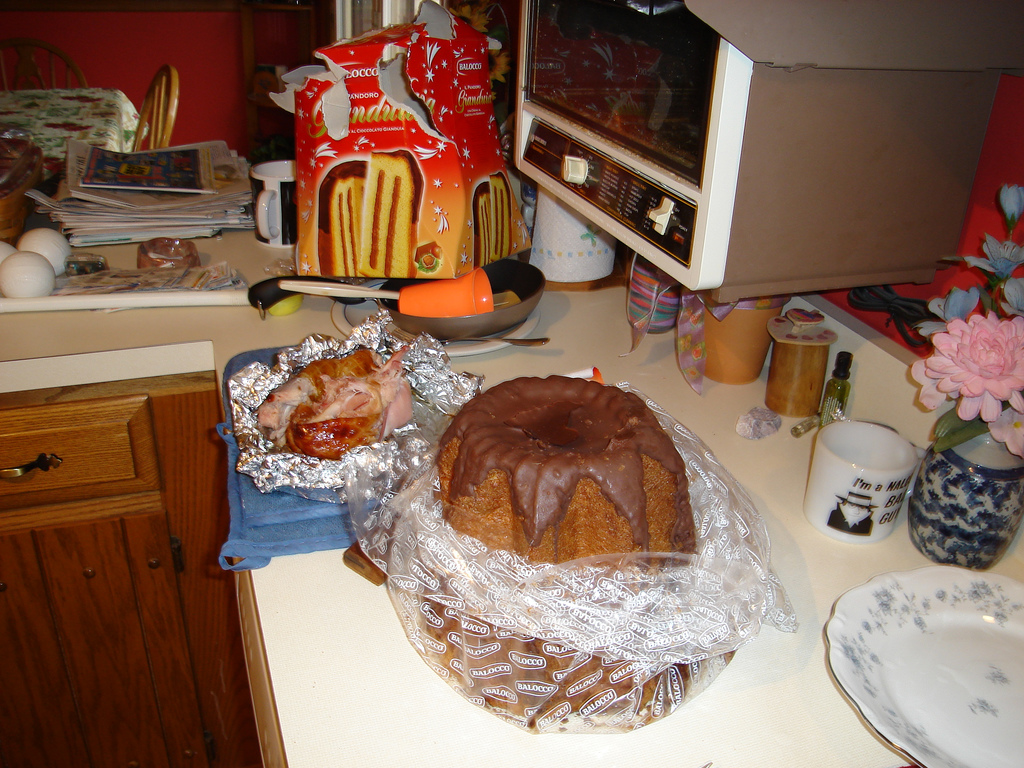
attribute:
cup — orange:
[375, 205, 523, 376]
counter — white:
[303, 674, 418, 748]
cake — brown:
[426, 350, 712, 577]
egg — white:
[9, 230, 92, 291]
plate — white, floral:
[822, 564, 1021, 753]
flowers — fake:
[910, 203, 1017, 359]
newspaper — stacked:
[87, 162, 237, 223]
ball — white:
[1, 212, 64, 290]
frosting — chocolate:
[441, 376, 653, 493]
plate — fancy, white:
[800, 582, 1006, 727]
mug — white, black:
[787, 424, 976, 587]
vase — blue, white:
[871, 448, 1016, 582]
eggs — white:
[1, 217, 112, 302]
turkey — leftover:
[243, 335, 445, 526]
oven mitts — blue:
[216, 409, 364, 587]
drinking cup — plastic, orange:
[397, 269, 497, 317]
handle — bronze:
[2, 446, 59, 481]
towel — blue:
[209, 336, 387, 572]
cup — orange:
[397, 262, 501, 323]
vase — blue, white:
[901, 420, 988, 524]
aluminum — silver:
[227, 320, 478, 508]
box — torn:
[287, 5, 527, 284]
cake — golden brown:
[417, 377, 722, 745]